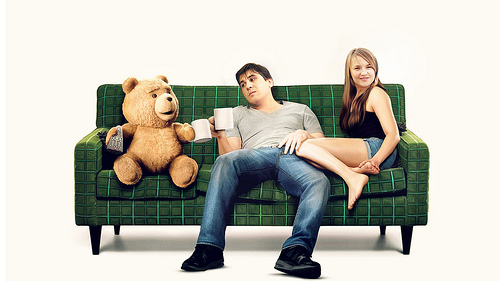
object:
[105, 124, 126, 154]
remote control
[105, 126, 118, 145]
hands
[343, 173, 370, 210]
feet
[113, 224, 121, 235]
legs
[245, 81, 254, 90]
nose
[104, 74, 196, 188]
bear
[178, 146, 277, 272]
legs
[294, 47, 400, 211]
girl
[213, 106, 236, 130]
cup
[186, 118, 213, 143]
cup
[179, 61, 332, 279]
boy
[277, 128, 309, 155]
hand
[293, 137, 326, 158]
knee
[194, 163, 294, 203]
pillow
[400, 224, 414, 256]
legs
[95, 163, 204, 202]
pillows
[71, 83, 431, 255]
couch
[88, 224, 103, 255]
legs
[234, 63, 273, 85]
hair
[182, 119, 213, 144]
mug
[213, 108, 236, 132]
mug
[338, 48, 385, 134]
hair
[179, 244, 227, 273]
shoe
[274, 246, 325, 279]
shoe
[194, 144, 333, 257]
jeans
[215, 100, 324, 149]
shirt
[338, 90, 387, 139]
shirt